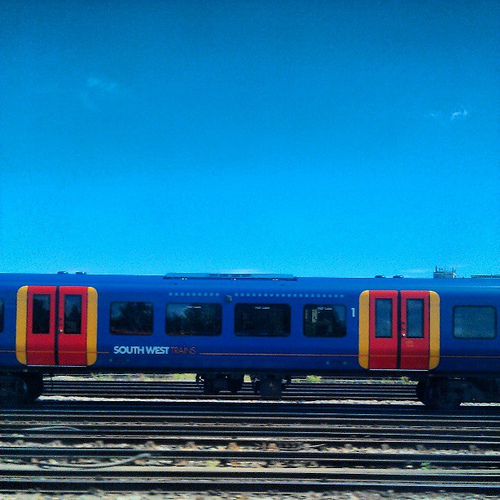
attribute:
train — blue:
[2, 266, 498, 408]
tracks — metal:
[6, 378, 499, 499]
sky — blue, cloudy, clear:
[0, 1, 499, 274]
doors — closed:
[13, 281, 111, 365]